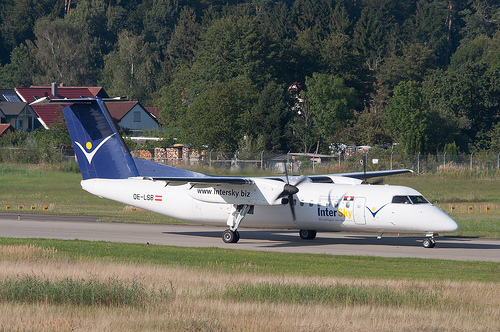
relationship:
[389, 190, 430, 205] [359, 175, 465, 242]
windows of cockpit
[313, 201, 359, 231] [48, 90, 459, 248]
name of plane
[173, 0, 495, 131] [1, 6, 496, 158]
leaves on trees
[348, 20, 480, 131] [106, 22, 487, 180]
leaves on trees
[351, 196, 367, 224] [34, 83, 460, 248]
door on airplane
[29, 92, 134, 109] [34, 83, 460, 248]
tailwing on airplane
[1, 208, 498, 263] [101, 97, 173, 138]
airport runway on house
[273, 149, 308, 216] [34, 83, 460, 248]
propeller on airplane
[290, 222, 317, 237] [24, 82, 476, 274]
wheels on airplane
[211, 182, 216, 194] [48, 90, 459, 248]
blue letter on plane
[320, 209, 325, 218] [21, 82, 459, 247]
letter on plane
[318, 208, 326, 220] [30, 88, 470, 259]
letter on plane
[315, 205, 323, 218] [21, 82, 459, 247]
letter on plane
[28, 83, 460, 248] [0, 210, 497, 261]
airplane on runway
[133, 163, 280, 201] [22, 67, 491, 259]
wing on airplane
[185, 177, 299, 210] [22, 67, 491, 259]
engine on side of airplane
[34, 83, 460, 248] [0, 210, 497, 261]
airplane on runway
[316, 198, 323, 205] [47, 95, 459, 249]
passenger windows on airplane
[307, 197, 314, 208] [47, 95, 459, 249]
passenger windows on airplane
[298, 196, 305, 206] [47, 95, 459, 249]
passenger windows on airplane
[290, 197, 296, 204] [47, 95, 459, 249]
passenger windows on airplane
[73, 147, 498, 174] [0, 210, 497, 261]
fencing along runway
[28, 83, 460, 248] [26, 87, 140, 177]
airplane with tail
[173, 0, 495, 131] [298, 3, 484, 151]
leaves in trees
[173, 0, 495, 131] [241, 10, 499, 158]
leaves in trees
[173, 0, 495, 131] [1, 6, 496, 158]
leaves in trees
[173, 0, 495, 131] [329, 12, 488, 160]
leaves in trees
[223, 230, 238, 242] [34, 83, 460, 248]
wheel on airplane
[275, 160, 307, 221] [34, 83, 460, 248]
propeller on airplane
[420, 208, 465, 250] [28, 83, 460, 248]
nose on airplane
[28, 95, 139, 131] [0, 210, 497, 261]
roof beside runway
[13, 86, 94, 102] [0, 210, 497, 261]
roof beside runway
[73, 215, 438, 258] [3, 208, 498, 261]
tarmac of airport runway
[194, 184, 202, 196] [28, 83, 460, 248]
letter on airplane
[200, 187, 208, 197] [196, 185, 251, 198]
letter on plane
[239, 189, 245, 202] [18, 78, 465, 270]
letter on plane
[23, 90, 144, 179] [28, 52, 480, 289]
tail on jet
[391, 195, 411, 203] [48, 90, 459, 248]
windows on plane